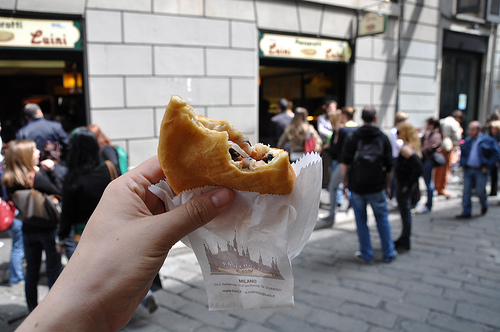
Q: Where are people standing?
A: In the street.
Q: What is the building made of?
A: Brick.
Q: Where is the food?
A: In a package.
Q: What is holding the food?
A: A hand.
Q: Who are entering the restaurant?
A: Crowd of people.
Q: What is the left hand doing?
A: Holding food.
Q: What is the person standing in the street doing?
A: He has food in the hand.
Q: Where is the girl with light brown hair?
A: To the left of the hand.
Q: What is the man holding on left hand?
A: Partially eaten pizza pocket.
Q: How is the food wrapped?
A: Pizza pocket paper.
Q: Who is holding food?
A: A person.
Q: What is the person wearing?
A: Blue jeans.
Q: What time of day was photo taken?
A: Taken in daytime.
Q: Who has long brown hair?
A: The woman.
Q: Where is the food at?
A: Small white bag.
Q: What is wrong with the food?
A: Bitten into.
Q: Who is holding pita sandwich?
A: A person.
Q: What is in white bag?
A: Food.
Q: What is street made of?
A: Bricks.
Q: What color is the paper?
A: White.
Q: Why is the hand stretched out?
A: To show the food.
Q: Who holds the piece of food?
A: A man.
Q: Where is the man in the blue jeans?
A: At the front.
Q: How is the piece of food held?
A: With one hand.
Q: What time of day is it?
A: Afternoon.